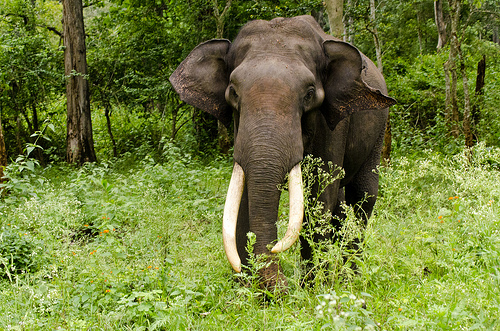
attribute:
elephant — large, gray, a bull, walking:
[167, 13, 398, 302]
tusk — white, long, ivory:
[270, 160, 306, 253]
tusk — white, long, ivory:
[221, 160, 247, 275]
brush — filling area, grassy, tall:
[1, 149, 499, 329]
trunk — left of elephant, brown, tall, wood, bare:
[60, 1, 98, 166]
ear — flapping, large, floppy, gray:
[322, 40, 398, 134]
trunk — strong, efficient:
[246, 168, 287, 302]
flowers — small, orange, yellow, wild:
[5, 193, 463, 318]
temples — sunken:
[293, 43, 324, 105]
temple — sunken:
[223, 46, 249, 117]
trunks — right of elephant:
[326, 0, 487, 161]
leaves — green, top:
[2, 115, 59, 209]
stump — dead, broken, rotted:
[0, 125, 14, 202]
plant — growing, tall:
[302, 153, 378, 297]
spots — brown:
[169, 66, 219, 117]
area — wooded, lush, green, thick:
[0, 0, 499, 168]